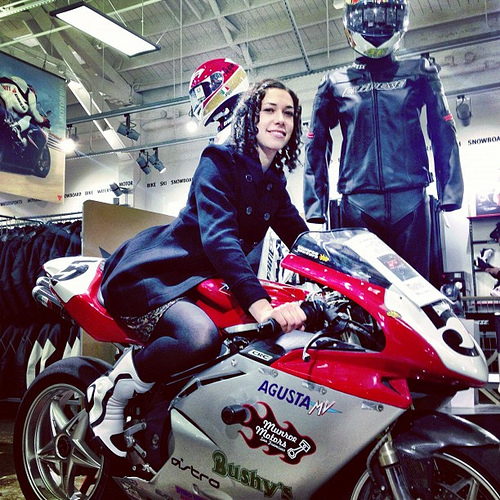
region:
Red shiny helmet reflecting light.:
[189, 58, 246, 123]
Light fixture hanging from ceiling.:
[54, 5, 158, 57]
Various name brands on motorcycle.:
[174, 375, 330, 492]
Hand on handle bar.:
[258, 303, 316, 340]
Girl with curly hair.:
[227, 79, 301, 172]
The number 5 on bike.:
[423, 293, 482, 370]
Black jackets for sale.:
[0, 316, 27, 398]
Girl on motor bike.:
[18, 83, 336, 460]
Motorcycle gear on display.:
[305, 0, 462, 223]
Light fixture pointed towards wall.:
[129, 147, 166, 177]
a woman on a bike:
[111, 73, 471, 425]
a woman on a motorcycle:
[86, 84, 426, 475]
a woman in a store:
[139, 93, 374, 464]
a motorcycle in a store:
[75, 154, 417, 486]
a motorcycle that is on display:
[50, 166, 465, 478]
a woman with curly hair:
[214, 73, 351, 180]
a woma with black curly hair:
[228, 59, 370, 198]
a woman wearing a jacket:
[158, 73, 362, 405]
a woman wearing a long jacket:
[99, 63, 315, 376]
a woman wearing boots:
[218, 118, 388, 436]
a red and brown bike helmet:
[185, 57, 247, 121]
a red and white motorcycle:
[21, 212, 493, 499]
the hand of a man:
[269, 299, 306, 332]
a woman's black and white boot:
[76, 350, 150, 460]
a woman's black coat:
[102, 140, 310, 313]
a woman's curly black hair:
[224, 78, 301, 170]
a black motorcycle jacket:
[304, 52, 466, 224]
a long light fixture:
[58, 4, 155, 63]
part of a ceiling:
[222, 6, 291, 36]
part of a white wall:
[138, 181, 190, 209]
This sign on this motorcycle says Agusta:
[269, 363, 326, 455]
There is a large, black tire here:
[46, 359, 80, 455]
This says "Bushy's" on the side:
[216, 446, 248, 498]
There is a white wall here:
[86, 178, 98, 223]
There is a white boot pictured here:
[99, 358, 125, 418]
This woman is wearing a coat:
[216, 159, 226, 188]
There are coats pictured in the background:
[30, 232, 65, 297]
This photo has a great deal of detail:
[106, 132, 243, 452]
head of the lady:
[211, 70, 333, 168]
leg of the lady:
[123, 282, 245, 397]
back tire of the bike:
[3, 344, 153, 497]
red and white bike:
[230, 347, 372, 458]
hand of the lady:
[241, 294, 315, 352]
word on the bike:
[243, 372, 320, 417]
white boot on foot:
[58, 346, 158, 458]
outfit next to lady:
[296, 32, 461, 210]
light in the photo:
[38, 101, 136, 180]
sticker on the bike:
[231, 399, 317, 478]